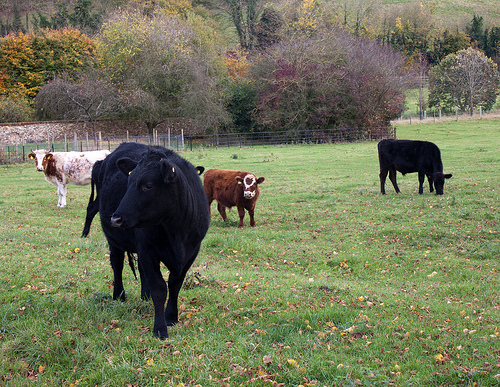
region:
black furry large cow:
[80, 143, 219, 334]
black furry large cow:
[376, 134, 448, 194]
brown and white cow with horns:
[27, 147, 116, 209]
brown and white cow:
[203, 168, 263, 226]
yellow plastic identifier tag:
[125, 167, 136, 177]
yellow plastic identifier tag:
[168, 165, 178, 172]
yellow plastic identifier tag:
[27, 153, 36, 161]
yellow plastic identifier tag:
[44, 152, 54, 162]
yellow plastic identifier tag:
[236, 177, 243, 186]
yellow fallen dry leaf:
[71, 243, 82, 257]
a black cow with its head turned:
[58, 141, 203, 346]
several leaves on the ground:
[248, 243, 435, 375]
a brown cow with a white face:
[208, 160, 273, 232]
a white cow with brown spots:
[1, 135, 117, 203]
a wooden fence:
[225, 117, 397, 157]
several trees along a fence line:
[12, 25, 482, 162]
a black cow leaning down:
[364, 126, 458, 216]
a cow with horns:
[16, 133, 61, 178]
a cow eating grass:
[392, 156, 460, 213]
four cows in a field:
[8, 118, 480, 298]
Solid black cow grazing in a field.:
[375, 136, 450, 193]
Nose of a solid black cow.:
[107, 213, 122, 229]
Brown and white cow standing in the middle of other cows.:
[201, 165, 264, 227]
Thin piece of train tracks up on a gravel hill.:
[0, 122, 149, 125]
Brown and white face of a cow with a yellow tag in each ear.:
[25, 149, 53, 174]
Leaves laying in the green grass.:
[434, 347, 449, 365]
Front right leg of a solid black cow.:
[133, 241, 167, 338]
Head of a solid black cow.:
[105, 151, 179, 232]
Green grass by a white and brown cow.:
[15, 179, 42, 194]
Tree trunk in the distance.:
[142, 118, 157, 143]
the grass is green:
[306, 285, 448, 376]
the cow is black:
[79, 151, 218, 299]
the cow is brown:
[207, 164, 284, 234]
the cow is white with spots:
[28, 137, 93, 193]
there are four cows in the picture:
[46, 123, 459, 272]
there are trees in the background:
[109, 53, 374, 97]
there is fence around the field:
[190, 121, 293, 152]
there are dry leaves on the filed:
[284, 318, 430, 370]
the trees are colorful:
[10, 28, 82, 75]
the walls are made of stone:
[43, 121, 100, 141]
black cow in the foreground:
[80, 134, 215, 349]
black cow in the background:
[374, 137, 455, 200]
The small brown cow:
[204, 161, 268, 223]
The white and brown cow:
[27, 139, 112, 205]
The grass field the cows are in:
[1, 119, 499, 386]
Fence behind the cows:
[2, 107, 499, 159]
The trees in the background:
[1, 0, 495, 130]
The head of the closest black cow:
[110, 144, 177, 236]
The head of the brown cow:
[236, 169, 268, 199]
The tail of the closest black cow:
[79, 162, 105, 242]